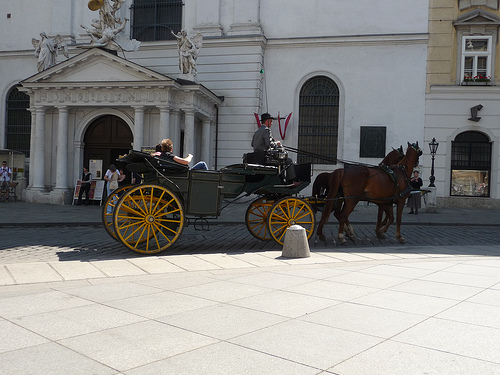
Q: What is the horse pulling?
A: A carriage.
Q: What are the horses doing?
A: They are pulling a cart with people on it.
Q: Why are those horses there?
A: Horses are there to pull a cart.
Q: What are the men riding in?
A: They ride in a chariot.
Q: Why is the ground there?
A: For people to walk on.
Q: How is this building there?
A: Skilled people built it.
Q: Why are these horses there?
A: To provide transportation to the riders.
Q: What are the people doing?
A: Enjoying the beautiful scenery.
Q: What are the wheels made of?
A: Wood.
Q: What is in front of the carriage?
A: Horses.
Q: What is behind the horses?
A: The carriage.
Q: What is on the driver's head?
A: A hat.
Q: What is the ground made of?
A: Slabs.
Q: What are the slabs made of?
A: Cement.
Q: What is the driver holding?
A: Reins.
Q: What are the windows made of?
A: Glass.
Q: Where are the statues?
A: On the building.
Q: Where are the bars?
A: On the windows.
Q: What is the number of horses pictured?
A: 2.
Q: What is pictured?
A: Horse drawn carriage.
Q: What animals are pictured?
A: Horses.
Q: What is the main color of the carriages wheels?
A: Yellow.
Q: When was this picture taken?
A: During the day.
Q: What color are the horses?
A: Brown.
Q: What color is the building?
A: White.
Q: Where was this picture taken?
A: Outside a building.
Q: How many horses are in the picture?
A: Two.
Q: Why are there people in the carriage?
A: They are taking a ride.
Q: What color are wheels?
A: Yellow.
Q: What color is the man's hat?
A: Black.